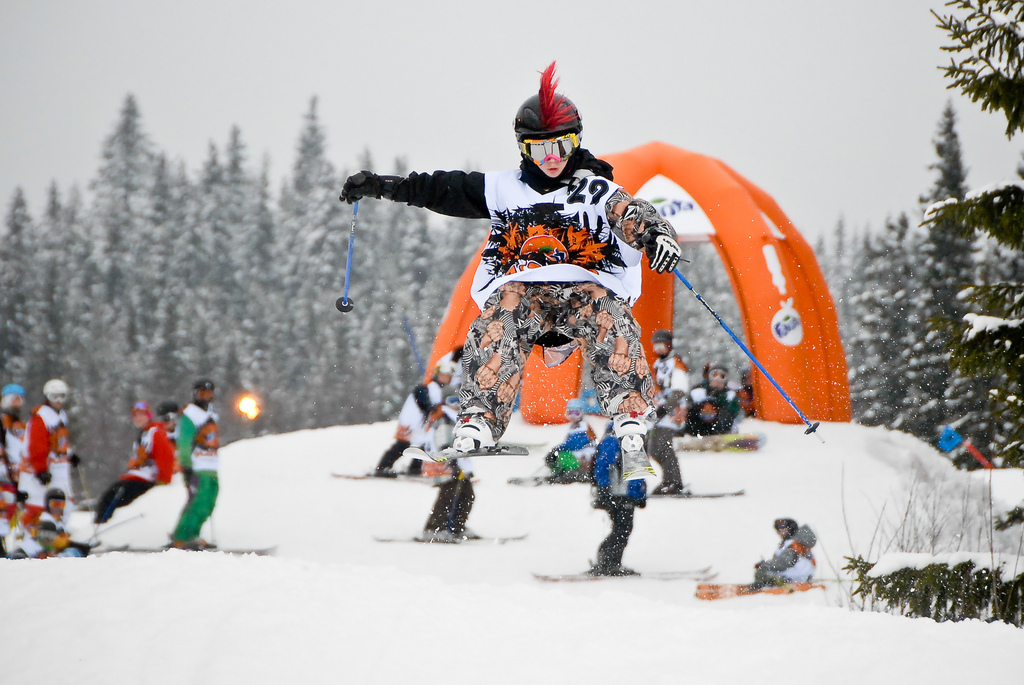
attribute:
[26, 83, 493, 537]
trees — evergreen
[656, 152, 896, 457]
dome — orange